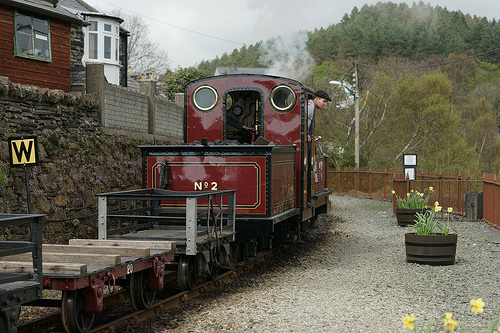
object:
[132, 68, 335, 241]
train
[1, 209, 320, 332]
track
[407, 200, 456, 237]
daffodil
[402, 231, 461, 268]
planter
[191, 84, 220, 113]
window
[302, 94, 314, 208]
door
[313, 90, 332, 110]
head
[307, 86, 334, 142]
man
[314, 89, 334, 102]
hat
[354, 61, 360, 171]
pole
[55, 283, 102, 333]
wheel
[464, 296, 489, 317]
flower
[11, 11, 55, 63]
window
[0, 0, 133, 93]
building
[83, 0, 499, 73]
sky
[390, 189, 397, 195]
flower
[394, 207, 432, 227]
planter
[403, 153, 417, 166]
sign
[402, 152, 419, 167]
frame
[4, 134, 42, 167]
sign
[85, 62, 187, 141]
barrier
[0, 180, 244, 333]
cars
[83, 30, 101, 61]
windows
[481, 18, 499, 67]
trees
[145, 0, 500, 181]
hill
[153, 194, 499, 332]
path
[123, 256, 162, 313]
wheels